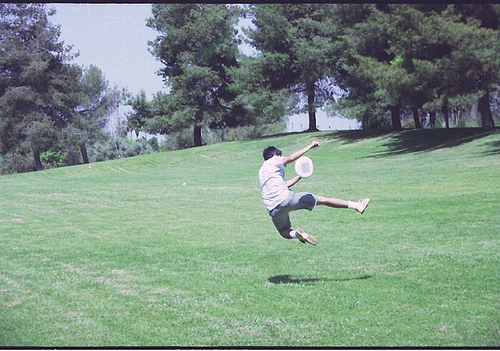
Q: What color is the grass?
A: Green.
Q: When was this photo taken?
A: During the day.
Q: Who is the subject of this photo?
A: The man.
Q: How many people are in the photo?
A: One.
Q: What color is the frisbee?
A: White.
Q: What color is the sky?
A: Blue.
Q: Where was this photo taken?
A: This photo was taken in a grasses lawn.